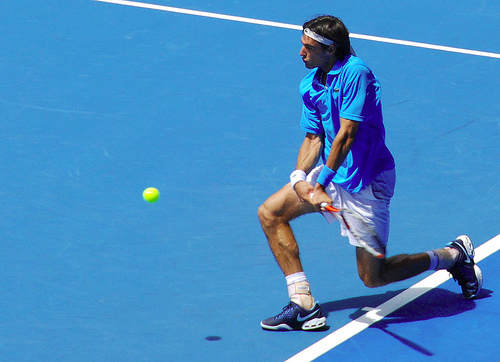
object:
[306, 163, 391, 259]
shorts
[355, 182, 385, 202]
pocket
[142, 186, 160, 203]
ball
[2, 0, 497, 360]
floor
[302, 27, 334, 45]
band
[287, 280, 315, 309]
brace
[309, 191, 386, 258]
racket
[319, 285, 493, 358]
shadow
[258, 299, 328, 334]
shoe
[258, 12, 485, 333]
man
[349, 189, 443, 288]
leg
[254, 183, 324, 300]
leg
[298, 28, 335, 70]
face